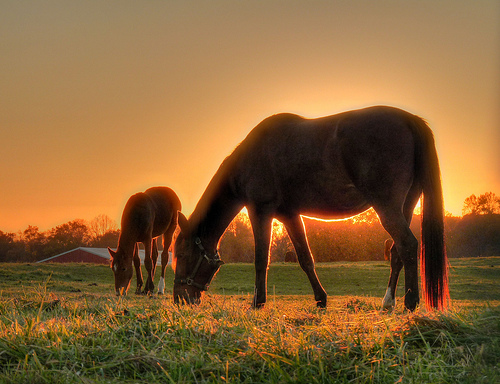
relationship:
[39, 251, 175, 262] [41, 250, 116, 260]
roof on building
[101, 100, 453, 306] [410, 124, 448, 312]
horses have tail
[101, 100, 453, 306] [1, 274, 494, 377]
horses eating grass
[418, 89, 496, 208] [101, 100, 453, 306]
sunset behind horses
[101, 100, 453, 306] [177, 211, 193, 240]
horses have ears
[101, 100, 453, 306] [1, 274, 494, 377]
horses in grass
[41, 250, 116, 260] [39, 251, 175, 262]
building has roof